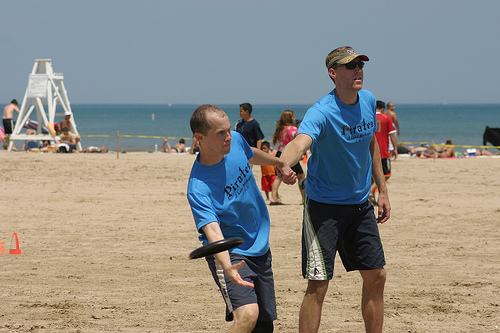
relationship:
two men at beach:
[180, 44, 402, 220] [57, 200, 163, 293]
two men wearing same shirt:
[180, 44, 402, 220] [183, 101, 418, 216]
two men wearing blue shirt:
[131, 2, 402, 220] [183, 101, 418, 216]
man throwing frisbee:
[162, 82, 283, 305] [172, 223, 258, 273]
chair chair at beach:
[13, 54, 84, 156] [57, 200, 163, 293]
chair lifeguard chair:
[13, 54, 84, 156] [13, 38, 48, 191]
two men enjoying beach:
[180, 44, 402, 220] [57, 200, 163, 293]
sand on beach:
[86, 158, 179, 315] [57, 200, 163, 293]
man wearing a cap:
[162, 82, 283, 305] [326, 44, 370, 68]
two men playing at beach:
[180, 44, 402, 220] [57, 200, 163, 293]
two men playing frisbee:
[131, 2, 402, 220] [172, 223, 258, 273]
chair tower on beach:
[13, 54, 84, 156] [57, 200, 163, 293]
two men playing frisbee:
[180, 44, 402, 220] [172, 223, 258, 273]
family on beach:
[218, 79, 305, 200] [57, 200, 163, 293]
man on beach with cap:
[162, 82, 283, 305] [326, 34, 378, 83]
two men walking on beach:
[180, 44, 402, 220] [57, 200, 163, 293]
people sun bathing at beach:
[397, 108, 460, 184] [57, 200, 163, 293]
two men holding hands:
[131, 2, 402, 220] [264, 119, 330, 219]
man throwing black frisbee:
[162, 82, 283, 305] [172, 223, 258, 273]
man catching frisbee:
[162, 82, 283, 305] [172, 223, 258, 273]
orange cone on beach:
[6, 224, 30, 267] [57, 200, 163, 293]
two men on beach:
[131, 2, 402, 220] [57, 200, 163, 293]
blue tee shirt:
[333, 100, 379, 194] [183, 101, 418, 216]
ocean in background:
[103, 103, 135, 133] [86, 98, 162, 129]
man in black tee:
[162, 82, 283, 305] [235, 115, 264, 138]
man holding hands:
[162, 82, 283, 305] [264, 119, 330, 219]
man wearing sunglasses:
[162, 82, 283, 305] [343, 64, 373, 72]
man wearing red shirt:
[162, 82, 283, 305] [183, 101, 418, 216]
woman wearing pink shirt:
[281, 109, 296, 144] [273, 108, 305, 142]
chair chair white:
[13, 54, 84, 156] [21, 36, 68, 145]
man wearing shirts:
[162, 82, 283, 305] [183, 101, 418, 216]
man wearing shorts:
[162, 82, 283, 305] [183, 206, 429, 315]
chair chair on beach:
[13, 54, 84, 156] [57, 200, 163, 293]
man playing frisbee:
[162, 82, 283, 305] [172, 223, 258, 273]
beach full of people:
[57, 200, 163, 293] [397, 108, 460, 184]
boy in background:
[258, 138, 274, 202] [86, 98, 162, 129]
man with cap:
[162, 82, 283, 305] [326, 44, 370, 68]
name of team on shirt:
[224, 162, 373, 216] [183, 101, 418, 216]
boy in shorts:
[258, 168, 295, 203] [257, 161, 304, 215]